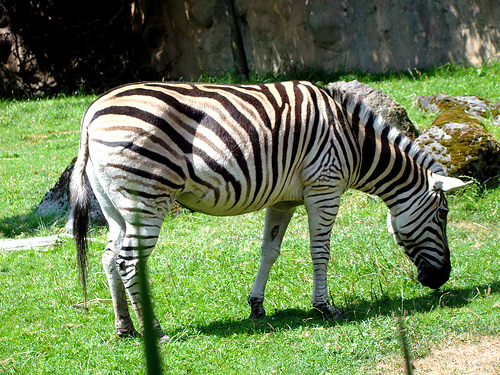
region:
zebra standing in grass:
[45, 58, 495, 368]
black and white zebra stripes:
[61, 60, 297, 194]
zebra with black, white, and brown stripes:
[78, 63, 300, 214]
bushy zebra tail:
[52, 109, 111, 310]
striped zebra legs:
[86, 211, 348, 343]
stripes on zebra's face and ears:
[375, 142, 487, 304]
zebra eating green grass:
[20, 75, 460, 350]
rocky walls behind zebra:
[16, 6, 461, 143]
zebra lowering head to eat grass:
[52, 56, 461, 355]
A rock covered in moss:
[414, 107, 499, 189]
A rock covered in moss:
[418, 92, 497, 119]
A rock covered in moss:
[40, 150, 105, 218]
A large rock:
[323, 78, 415, 132]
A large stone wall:
[4, 0, 498, 99]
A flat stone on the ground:
[3, 227, 61, 252]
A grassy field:
[5, 66, 497, 371]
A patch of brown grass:
[383, 335, 497, 374]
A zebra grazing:
[66, 79, 473, 339]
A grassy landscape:
[0, 67, 495, 373]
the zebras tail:
[66, 158, 93, 290]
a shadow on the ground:
[215, 311, 327, 336]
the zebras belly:
[191, 160, 286, 209]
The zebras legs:
[251, 243, 335, 314]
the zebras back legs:
[106, 235, 153, 335]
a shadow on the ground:
[9, 200, 54, 235]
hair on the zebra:
[348, 96, 393, 129]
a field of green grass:
[0, 99, 62, 170]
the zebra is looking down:
[402, 194, 462, 287]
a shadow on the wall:
[306, 19, 483, 74]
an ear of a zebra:
[434, 167, 477, 198]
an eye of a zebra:
[436, 205, 453, 222]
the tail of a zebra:
[69, 121, 94, 313]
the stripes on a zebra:
[264, 100, 330, 167]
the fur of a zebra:
[132, 98, 186, 172]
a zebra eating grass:
[339, 90, 469, 294]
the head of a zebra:
[382, 161, 473, 291]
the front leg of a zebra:
[300, 184, 341, 310]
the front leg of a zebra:
[244, 200, 299, 317]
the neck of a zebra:
[344, 92, 416, 201]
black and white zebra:
[77, 74, 460, 333]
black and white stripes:
[149, 85, 324, 207]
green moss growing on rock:
[427, 94, 497, 178]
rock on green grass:
[412, 88, 498, 178]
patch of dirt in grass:
[392, 325, 498, 370]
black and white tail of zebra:
[65, 128, 106, 299]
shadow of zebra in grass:
[170, 278, 498, 326]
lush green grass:
[10, 272, 108, 374]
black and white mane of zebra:
[330, 82, 449, 214]